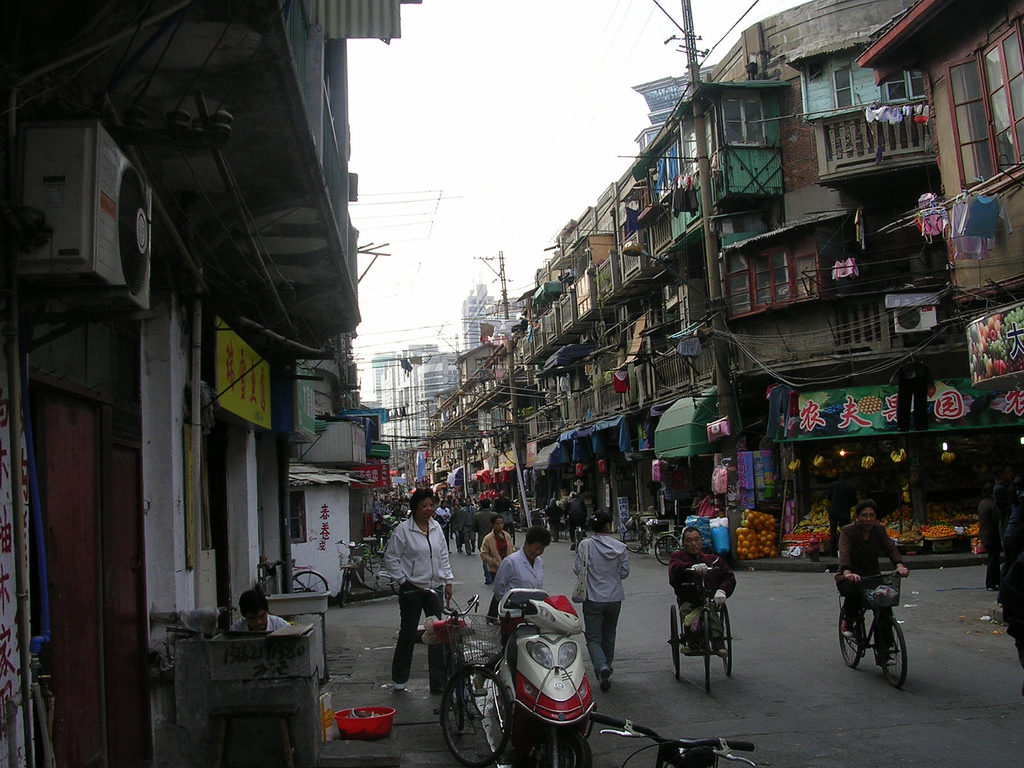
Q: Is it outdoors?
A: Yes, it is outdoors.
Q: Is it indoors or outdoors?
A: It is outdoors.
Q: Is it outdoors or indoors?
A: It is outdoors.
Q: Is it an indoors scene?
A: No, it is outdoors.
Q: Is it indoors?
A: No, it is outdoors.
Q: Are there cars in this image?
A: No, there are no cars.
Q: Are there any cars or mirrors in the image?
A: No, there are no cars or mirrors.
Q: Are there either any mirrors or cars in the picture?
A: No, there are no cars or mirrors.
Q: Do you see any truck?
A: No, there are no trucks.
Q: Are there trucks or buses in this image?
A: No, there are no trucks or buses.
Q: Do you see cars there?
A: No, there are no cars.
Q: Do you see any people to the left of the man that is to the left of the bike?
A: Yes, there are people to the left of the man.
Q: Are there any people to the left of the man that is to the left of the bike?
A: Yes, there are people to the left of the man.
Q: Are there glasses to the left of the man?
A: No, there are people to the left of the man.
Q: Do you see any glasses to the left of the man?
A: No, there are people to the left of the man.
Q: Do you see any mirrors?
A: No, there are no mirrors.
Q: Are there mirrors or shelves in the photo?
A: No, there are no mirrors or shelves.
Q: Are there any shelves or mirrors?
A: No, there are no mirrors or shelves.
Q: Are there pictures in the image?
A: No, there are no pictures.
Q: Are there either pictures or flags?
A: No, there are no pictures or flags.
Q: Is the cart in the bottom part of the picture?
A: Yes, the cart is in the bottom of the image.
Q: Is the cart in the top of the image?
A: No, the cart is in the bottom of the image.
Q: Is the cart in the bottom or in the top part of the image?
A: The cart is in the bottom of the image.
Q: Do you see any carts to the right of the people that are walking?
A: Yes, there is a cart to the right of the people.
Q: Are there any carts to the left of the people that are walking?
A: No, the cart is to the right of the people.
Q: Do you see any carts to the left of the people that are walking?
A: No, the cart is to the right of the people.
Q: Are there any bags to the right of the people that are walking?
A: No, there is a cart to the right of the people.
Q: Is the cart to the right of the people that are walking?
A: Yes, the cart is to the right of the people.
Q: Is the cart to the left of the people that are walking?
A: No, the cart is to the right of the people.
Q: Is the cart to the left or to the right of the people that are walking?
A: The cart is to the right of the people.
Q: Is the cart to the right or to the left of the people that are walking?
A: The cart is to the right of the people.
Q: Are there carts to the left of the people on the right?
A: Yes, there is a cart to the left of the people.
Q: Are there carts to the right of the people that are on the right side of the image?
A: No, the cart is to the left of the people.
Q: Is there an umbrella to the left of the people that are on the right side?
A: No, there is a cart to the left of the people.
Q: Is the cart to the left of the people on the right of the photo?
A: Yes, the cart is to the left of the people.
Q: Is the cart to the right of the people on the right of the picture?
A: No, the cart is to the left of the people.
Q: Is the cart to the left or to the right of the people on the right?
A: The cart is to the left of the people.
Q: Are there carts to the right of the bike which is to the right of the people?
A: Yes, there is a cart to the right of the bike.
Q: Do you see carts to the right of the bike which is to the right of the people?
A: Yes, there is a cart to the right of the bike.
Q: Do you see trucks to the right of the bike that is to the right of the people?
A: No, there is a cart to the right of the bike.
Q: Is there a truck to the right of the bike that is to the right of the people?
A: No, there is a cart to the right of the bike.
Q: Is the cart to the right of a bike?
A: Yes, the cart is to the right of a bike.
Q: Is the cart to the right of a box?
A: No, the cart is to the right of a bike.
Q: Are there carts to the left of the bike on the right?
A: Yes, there is a cart to the left of the bike.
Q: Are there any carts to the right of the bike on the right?
A: No, the cart is to the left of the bike.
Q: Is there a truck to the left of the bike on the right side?
A: No, there is a cart to the left of the bike.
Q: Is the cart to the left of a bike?
A: Yes, the cart is to the left of a bike.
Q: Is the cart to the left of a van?
A: No, the cart is to the left of a bike.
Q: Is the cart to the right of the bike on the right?
A: No, the cart is to the left of the bike.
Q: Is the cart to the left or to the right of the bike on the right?
A: The cart is to the left of the bike.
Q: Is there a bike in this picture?
A: Yes, there is a bike.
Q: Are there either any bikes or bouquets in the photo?
A: Yes, there is a bike.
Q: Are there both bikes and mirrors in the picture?
A: No, there is a bike but no mirrors.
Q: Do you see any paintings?
A: No, there are no paintings.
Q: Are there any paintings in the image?
A: No, there are no paintings.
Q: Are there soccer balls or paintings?
A: No, there are no paintings or soccer balls.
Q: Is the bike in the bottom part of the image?
A: Yes, the bike is in the bottom of the image.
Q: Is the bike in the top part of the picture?
A: No, the bike is in the bottom of the image.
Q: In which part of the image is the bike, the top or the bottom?
A: The bike is in the bottom of the image.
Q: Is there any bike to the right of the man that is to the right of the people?
A: Yes, there is a bike to the right of the man.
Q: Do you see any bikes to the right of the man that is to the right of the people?
A: Yes, there is a bike to the right of the man.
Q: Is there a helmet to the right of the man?
A: No, there is a bike to the right of the man.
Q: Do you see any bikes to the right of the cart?
A: Yes, there is a bike to the right of the cart.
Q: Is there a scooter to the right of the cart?
A: No, there is a bike to the right of the cart.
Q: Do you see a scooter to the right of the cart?
A: No, there is a bike to the right of the cart.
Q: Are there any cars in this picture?
A: No, there are no cars.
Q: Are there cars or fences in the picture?
A: No, there are no cars or fences.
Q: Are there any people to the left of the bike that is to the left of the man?
A: Yes, there are people to the left of the bike.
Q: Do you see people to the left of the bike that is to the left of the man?
A: Yes, there are people to the left of the bike.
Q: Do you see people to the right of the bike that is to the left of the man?
A: No, the people are to the left of the bike.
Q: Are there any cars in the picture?
A: No, there are no cars.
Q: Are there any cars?
A: No, there are no cars.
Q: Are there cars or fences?
A: No, there are no cars or fences.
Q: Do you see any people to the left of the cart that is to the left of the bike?
A: Yes, there are people to the left of the cart.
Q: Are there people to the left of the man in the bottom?
A: Yes, there are people to the left of the man.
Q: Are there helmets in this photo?
A: No, there are no helmets.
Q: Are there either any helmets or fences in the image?
A: No, there are no helmets or fences.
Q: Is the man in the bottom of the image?
A: Yes, the man is in the bottom of the image.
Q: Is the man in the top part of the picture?
A: No, the man is in the bottom of the image.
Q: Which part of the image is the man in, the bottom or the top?
A: The man is in the bottom of the image.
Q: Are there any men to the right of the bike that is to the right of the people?
A: Yes, there is a man to the right of the bike.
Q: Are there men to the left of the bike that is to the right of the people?
A: No, the man is to the right of the bike.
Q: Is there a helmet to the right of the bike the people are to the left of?
A: No, there is a man to the right of the bike.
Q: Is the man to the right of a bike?
A: Yes, the man is to the right of a bike.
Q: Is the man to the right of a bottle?
A: No, the man is to the right of a bike.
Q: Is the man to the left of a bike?
A: No, the man is to the right of a bike.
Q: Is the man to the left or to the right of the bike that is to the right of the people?
A: The man is to the right of the bike.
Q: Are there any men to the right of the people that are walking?
A: Yes, there is a man to the right of the people.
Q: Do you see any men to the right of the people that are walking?
A: Yes, there is a man to the right of the people.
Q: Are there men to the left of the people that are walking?
A: No, the man is to the right of the people.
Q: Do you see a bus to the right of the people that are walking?
A: No, there is a man to the right of the people.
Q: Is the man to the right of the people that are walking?
A: Yes, the man is to the right of the people.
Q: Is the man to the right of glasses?
A: No, the man is to the right of the people.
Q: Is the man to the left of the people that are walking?
A: No, the man is to the right of the people.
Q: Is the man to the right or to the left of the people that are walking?
A: The man is to the right of the people.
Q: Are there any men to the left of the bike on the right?
A: Yes, there is a man to the left of the bike.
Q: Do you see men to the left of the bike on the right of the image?
A: Yes, there is a man to the left of the bike.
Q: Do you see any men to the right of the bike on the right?
A: No, the man is to the left of the bike.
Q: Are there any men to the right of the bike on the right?
A: No, the man is to the left of the bike.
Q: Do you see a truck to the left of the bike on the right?
A: No, there is a man to the left of the bike.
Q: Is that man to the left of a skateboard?
A: No, the man is to the left of a bike.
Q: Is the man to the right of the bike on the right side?
A: No, the man is to the left of the bike.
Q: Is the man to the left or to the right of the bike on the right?
A: The man is to the left of the bike.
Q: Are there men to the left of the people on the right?
A: Yes, there is a man to the left of the people.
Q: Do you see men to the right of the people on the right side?
A: No, the man is to the left of the people.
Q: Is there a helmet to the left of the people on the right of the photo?
A: No, there is a man to the left of the people.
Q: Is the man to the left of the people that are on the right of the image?
A: Yes, the man is to the left of the people.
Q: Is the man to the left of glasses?
A: No, the man is to the left of the people.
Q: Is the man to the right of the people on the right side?
A: No, the man is to the left of the people.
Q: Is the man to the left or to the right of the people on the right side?
A: The man is to the left of the people.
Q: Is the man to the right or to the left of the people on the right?
A: The man is to the left of the people.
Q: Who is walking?
A: The people are walking.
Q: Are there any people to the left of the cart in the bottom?
A: Yes, there are people to the left of the cart.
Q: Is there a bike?
A: Yes, there is a bike.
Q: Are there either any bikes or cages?
A: Yes, there is a bike.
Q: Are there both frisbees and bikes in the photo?
A: No, there is a bike but no frisbees.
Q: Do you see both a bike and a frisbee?
A: No, there is a bike but no frisbees.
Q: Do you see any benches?
A: No, there are no benches.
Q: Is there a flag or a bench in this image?
A: No, there are no benches or flags.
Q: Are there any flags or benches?
A: No, there are no benches or flags.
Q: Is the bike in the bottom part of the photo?
A: Yes, the bike is in the bottom of the image.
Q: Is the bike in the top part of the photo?
A: No, the bike is in the bottom of the image.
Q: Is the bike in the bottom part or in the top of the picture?
A: The bike is in the bottom of the image.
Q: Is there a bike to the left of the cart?
A: Yes, there is a bike to the left of the cart.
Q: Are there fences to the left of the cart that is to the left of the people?
A: No, there is a bike to the left of the cart.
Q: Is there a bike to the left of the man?
A: Yes, there is a bike to the left of the man.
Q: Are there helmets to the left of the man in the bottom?
A: No, there is a bike to the left of the man.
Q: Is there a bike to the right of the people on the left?
A: Yes, there is a bike to the right of the people.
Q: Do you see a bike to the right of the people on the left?
A: Yes, there is a bike to the right of the people.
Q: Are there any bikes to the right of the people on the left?
A: Yes, there is a bike to the right of the people.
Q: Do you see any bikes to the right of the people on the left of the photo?
A: Yes, there is a bike to the right of the people.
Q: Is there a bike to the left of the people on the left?
A: No, the bike is to the right of the people.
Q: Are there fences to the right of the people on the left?
A: No, there is a bike to the right of the people.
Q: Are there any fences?
A: No, there are no fences.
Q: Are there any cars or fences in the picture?
A: No, there are no fences or cars.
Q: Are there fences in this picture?
A: No, there are no fences.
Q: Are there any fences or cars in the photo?
A: No, there are no fences or cars.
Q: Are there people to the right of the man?
A: Yes, there are people to the right of the man.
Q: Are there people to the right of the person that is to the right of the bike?
A: Yes, there are people to the right of the man.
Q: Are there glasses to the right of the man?
A: No, there are people to the right of the man.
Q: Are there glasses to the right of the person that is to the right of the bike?
A: No, there are people to the right of the man.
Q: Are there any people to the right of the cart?
A: Yes, there are people to the right of the cart.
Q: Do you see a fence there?
A: No, there are no fences.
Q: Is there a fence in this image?
A: No, there are no fences.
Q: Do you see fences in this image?
A: No, there are no fences.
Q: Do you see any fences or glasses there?
A: No, there are no fences or glasses.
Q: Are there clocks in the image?
A: No, there are no clocks.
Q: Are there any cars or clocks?
A: No, there are no clocks or cars.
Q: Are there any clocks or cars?
A: No, there are no clocks or cars.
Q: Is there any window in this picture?
A: Yes, there is a window.